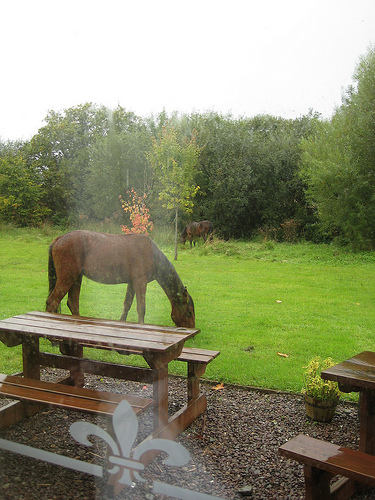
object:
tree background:
[118, 183, 141, 229]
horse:
[180, 220, 214, 249]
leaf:
[211, 382, 226, 392]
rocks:
[0, 365, 360, 498]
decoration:
[67, 397, 190, 487]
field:
[0, 219, 375, 403]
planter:
[304, 392, 337, 423]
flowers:
[304, 351, 340, 397]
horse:
[45, 230, 196, 349]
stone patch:
[2, 357, 374, 497]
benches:
[0, 368, 155, 498]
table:
[0, 313, 201, 499]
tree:
[298, 42, 375, 248]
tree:
[249, 108, 324, 243]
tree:
[1, 141, 51, 230]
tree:
[119, 188, 155, 236]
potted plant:
[301, 355, 340, 419]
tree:
[144, 124, 204, 261]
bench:
[278, 429, 375, 497]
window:
[0, 4, 373, 497]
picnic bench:
[52, 341, 217, 421]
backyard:
[0, 217, 373, 498]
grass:
[0, 223, 373, 400]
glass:
[1, 6, 371, 498]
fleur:
[68, 398, 192, 485]